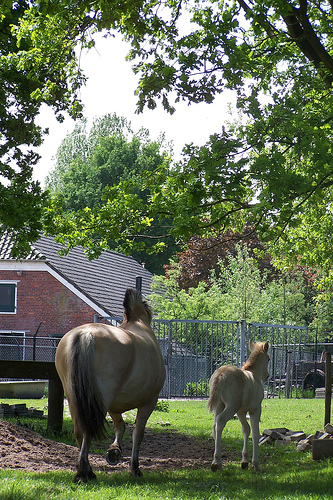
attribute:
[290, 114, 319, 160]
leaves — green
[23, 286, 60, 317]
bricks — red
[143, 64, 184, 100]
leaves — green 